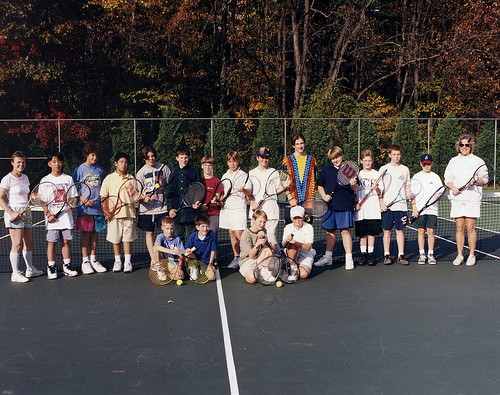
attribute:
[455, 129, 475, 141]
hair — short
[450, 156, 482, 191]
shirt — white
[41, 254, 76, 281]
laces — black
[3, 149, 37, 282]
kid — standing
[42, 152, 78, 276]
kid — standing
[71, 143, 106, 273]
kid — standing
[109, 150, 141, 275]
kid — standing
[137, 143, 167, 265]
kid — standing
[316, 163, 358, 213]
shirt — blue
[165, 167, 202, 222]
shirt — blue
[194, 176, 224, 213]
shirt — blue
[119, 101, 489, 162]
evergreen trees — green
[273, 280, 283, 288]
ball — yellow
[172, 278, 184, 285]
ball — yellow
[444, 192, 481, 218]
skirt — white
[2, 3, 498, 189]
trees — tall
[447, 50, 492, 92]
leaves — colorful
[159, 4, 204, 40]
leaves — colorful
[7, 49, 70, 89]
leaves — colorful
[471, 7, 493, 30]
leaves — colorful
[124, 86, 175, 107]
leaves — colorful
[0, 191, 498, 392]
tennis court — gray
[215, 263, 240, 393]
stripe — white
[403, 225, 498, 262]
stripe — white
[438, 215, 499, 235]
stripe — white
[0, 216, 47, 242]
stripe — white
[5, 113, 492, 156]
fence — metal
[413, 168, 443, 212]
shirt — white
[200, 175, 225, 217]
shirt — red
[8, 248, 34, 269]
socks — white